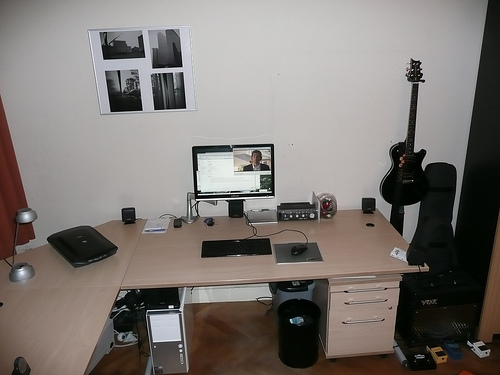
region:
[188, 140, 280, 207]
a computer monitor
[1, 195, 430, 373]
a brown wooden desk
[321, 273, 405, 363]
the drawers of a desk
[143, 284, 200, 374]
a gray computer tower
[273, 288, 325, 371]
a black trash can on the floor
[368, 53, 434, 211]
a guitar on the wall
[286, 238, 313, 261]
a black computer mouse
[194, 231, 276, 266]
a black computer keyboard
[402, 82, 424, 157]
the neck of a guitar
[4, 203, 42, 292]
a gray lamp on the desk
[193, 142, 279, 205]
computer screen turned on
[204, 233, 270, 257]
black keyboard on desk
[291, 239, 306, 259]
black mouse on desk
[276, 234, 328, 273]
grey mouse pad on desk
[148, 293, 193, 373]
computer tower on ground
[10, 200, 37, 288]
silver lamp on desk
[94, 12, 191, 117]
painting hanging from wall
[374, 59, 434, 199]
black guitar on wall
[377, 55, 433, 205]
electric guitar on wall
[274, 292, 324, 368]
black trashcan on floor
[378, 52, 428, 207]
a black guitar hanging on wall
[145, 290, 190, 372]
an Apple Mac Pro tower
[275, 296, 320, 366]
a black trash can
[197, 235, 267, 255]
a black wired computer keyboard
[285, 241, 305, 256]
a black wired mouse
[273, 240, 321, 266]
a silver mouse pad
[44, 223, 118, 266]
a black flatbed scanner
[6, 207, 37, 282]
a silver desk lamp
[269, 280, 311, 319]
a silver and black paper shredder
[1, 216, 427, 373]
a light brown corner desk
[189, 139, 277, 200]
A black framed flatscreen computer monitor.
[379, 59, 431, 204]
A black guitar hanging on the wall.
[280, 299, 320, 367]
A black trash bin.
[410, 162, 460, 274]
A dark grey guitar case.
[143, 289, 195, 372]
A silver and white computer processing unit.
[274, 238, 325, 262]
A grey mousepad.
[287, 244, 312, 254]
A black mouse.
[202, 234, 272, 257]
A black computer keyboard.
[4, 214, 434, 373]
A light brown wooden desk.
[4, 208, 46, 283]
A silver small desk lamp.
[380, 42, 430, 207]
a small black guitar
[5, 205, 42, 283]
a small gray desk lamp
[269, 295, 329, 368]
a small black trashcan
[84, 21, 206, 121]
a large gray picture frame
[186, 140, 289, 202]
a large computer monitor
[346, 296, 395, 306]
a gray drawer handle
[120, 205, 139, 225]
a small computer speaker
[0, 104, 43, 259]
part of a red curtain